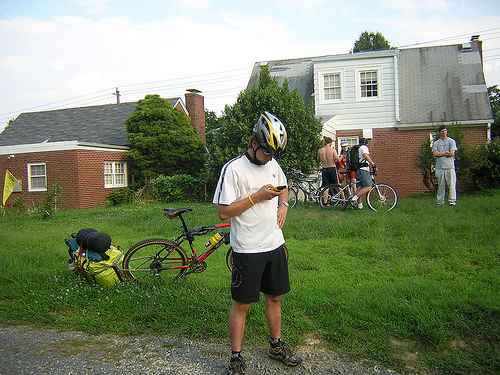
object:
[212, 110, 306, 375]
man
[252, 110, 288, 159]
helmet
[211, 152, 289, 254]
shirt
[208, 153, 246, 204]
stripe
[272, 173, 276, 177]
logo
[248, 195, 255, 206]
wristband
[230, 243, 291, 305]
shorts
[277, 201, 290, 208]
watch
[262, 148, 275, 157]
glasses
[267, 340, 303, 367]
shoes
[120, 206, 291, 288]
bike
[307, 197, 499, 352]
grass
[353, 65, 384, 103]
window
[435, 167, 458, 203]
pants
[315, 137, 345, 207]
man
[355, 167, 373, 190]
shorts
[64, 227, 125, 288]
backpack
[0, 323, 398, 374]
road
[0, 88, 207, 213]
house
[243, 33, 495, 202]
house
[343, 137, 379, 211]
men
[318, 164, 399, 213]
bikes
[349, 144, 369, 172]
backpack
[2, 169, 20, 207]
flag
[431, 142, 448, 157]
arms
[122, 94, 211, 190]
trees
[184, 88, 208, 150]
chimney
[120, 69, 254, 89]
power lines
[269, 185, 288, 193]
cellphone